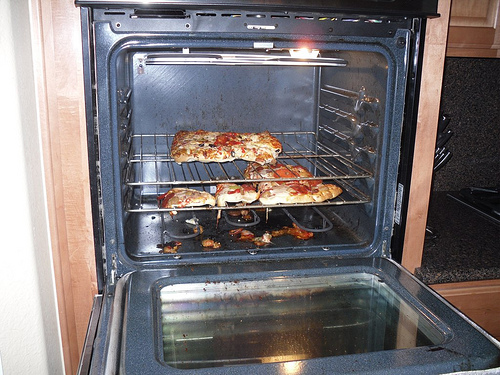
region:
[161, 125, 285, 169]
chicken baking in oven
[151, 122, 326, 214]
four pieces of chicken in oven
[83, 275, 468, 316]
blue oven door with window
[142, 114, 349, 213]
four pieces of chicken being baked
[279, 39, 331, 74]
light being reflected from camera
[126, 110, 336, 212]
chicken being cooked in oven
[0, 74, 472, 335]
oven that's built into kitchen wall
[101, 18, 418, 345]
open oven with chicken inside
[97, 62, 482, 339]
oven cooking food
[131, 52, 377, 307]
four pieces of food cooking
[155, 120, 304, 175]
pizza in the oven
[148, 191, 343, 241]
coils of the oven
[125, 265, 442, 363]
the clear window of the oven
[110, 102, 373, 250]
silver oven racks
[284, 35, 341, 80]
a bright light in the oven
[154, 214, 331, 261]
food spilled on the oven bottom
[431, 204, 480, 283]
a counter top next to the oven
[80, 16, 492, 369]
an oven with pizza spilled in it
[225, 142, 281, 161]
melted white cheese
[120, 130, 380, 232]
adjustable silver racks in the oven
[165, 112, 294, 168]
pizza on top rack of stove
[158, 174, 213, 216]
small piece of pizza on bottom shelf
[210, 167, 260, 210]
small piece of pizza on bottom shelf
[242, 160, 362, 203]
large piece of pizza on bottom shelf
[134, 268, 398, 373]
glass window in stove door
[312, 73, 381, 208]
adjustable rack grids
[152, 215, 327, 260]
pizza droppings from shelves above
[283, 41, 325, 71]
light inside stove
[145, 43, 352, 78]
upper burning inside stove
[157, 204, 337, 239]
bottom burners inside stove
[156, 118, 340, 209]
Pizza in the oven.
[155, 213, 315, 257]
Cheese that has dripped onto the bottom of the oven and burned.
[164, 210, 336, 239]
Electric heating coils.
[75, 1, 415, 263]
Inside of an oven.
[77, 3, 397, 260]
Open oven.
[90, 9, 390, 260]
Oven containing pizza.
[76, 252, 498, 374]
Open oven door.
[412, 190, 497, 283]
Portion of a kitchen counter.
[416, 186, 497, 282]
Speckled granite countertop.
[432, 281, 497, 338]
Wooden kitchen drawer.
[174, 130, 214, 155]
pizza with assorted toppings cooking in oven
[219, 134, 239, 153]
pizza with assorted toppings cooking in oven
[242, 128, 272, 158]
pizza with assorted toppings cooking in oven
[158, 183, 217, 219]
pizza with assorted toppings cooking in oven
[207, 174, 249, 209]
pizza with assorted toppings cooking in oven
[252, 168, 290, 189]
pizza with assorted toppings cooking in oven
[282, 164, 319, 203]
pizza with assorted toppings cooking in oven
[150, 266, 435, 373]
gray open oven door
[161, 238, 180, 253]
pieces of toppings from pizza on bottom of oven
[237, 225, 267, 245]
pieces of toppings from pizza on bottom of oven